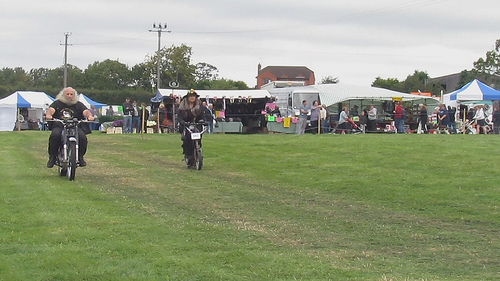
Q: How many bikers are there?
A: 2.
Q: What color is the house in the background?
A: Brown.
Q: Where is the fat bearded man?
A: On the motorcycle.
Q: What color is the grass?
A: Green.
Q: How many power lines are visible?
A: 2.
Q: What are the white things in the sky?
A: Clouds.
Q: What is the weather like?
A: Overcast.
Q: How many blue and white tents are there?
A: 3.